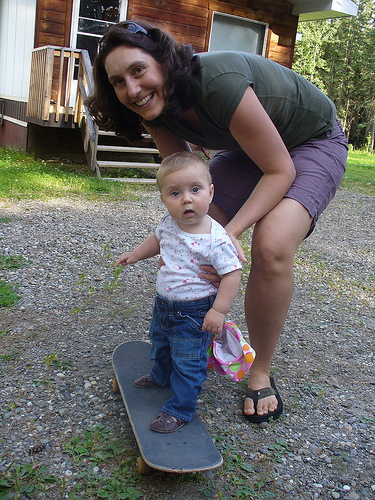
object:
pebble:
[323, 491, 342, 499]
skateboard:
[111, 341, 222, 471]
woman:
[83, 22, 349, 424]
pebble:
[322, 448, 333, 462]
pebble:
[274, 474, 286, 491]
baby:
[114, 151, 242, 434]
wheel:
[136, 455, 149, 476]